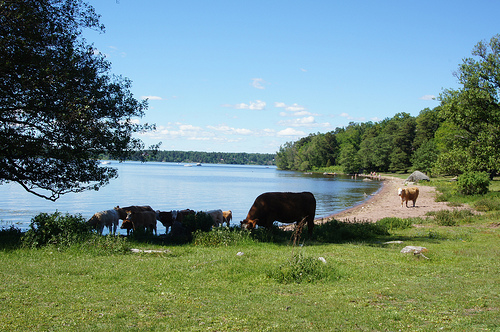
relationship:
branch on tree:
[3, 172, 64, 204] [0, 0, 158, 201]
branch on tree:
[0, 173, 67, 202] [5, 2, 140, 205]